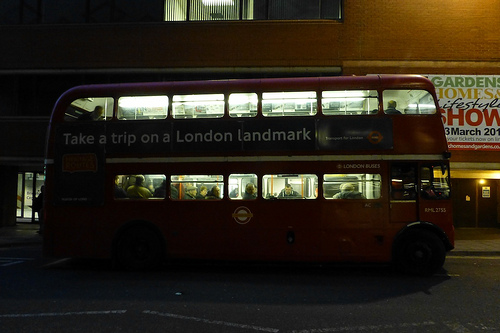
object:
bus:
[37, 72, 456, 279]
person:
[242, 181, 258, 200]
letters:
[61, 132, 72, 146]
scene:
[0, 1, 499, 333]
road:
[1, 254, 500, 333]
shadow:
[0, 263, 450, 303]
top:
[43, 72, 448, 161]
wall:
[0, 0, 498, 71]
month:
[450, 126, 481, 136]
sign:
[419, 74, 499, 151]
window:
[259, 87, 318, 117]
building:
[0, 1, 499, 226]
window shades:
[163, 0, 254, 23]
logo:
[229, 205, 254, 226]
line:
[0, 307, 127, 320]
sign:
[58, 117, 391, 155]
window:
[252, 1, 341, 22]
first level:
[42, 159, 456, 268]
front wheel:
[393, 228, 447, 277]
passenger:
[276, 184, 303, 199]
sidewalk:
[443, 226, 499, 256]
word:
[174, 127, 234, 143]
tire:
[116, 225, 161, 273]